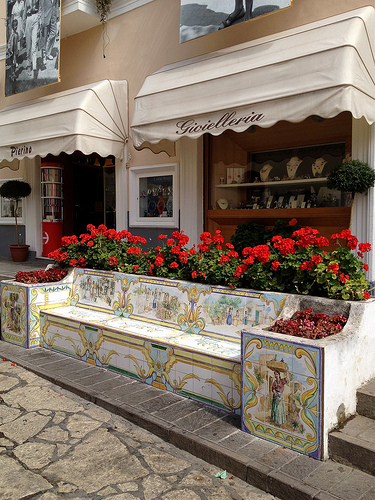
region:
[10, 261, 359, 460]
An old cement bench with paintings on it.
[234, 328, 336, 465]
The painting of a woman with a basket on her head.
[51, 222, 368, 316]
Red potted flowers on top of the bench.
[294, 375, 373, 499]
Steps leading up to the shops.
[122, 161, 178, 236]
A window with watches on display.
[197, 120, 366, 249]
A window display with jewelry in it.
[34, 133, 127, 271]
The entrance to the shops.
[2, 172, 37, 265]
A potted tree by the entrance.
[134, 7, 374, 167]
A window awning for Gioielleria.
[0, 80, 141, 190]
A window awning for Pierino.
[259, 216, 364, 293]
geraniums in full bloom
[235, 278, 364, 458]
ornate tile and masonry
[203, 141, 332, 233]
shop window jewlery display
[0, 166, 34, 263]
potted topiary evergreen tree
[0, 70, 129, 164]
custom outdoor shop awning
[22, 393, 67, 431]
outdoor flagstone street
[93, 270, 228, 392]
scenic tiled outdoor bench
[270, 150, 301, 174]
necklace on display easel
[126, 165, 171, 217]
outside shop window watch display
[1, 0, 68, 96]
outdoor hanging monochromatic artwork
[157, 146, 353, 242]
jewelry in a store window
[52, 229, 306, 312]
Red flowers on the back of a bench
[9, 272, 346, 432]
A tile bench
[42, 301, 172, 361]
The seat of a bench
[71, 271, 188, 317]
The back of a bench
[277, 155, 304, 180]
A necklace in a store window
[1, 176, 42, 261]
A tree in a pot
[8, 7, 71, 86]
A black and white picture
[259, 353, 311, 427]
A woman with a basket on her head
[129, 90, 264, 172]
A white awning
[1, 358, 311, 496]
the street next to the building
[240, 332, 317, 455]
a picture in the tiles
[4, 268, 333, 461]
a bench with a lot of colorful tiles on it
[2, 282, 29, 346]
another painting made out of tiles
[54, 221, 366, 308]
red flowers growing on top of the bench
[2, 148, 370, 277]
two buildings behind the bench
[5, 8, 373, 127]
the awnings above the stores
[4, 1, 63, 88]
a poster above the building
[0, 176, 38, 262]
a tree next to the store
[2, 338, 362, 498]
the sidewalk in front of the bench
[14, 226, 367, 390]
Ornate vintage planted seating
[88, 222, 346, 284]
Red geraniums healthy plants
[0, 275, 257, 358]
Hand painted artwork bench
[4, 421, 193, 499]
Inlaid stone covers street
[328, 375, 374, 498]
Right brick stairs descend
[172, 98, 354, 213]
Awning jewelry shop Gioielleria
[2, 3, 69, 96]
Large black white photo hangs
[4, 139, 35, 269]
Potted tree outside Pierino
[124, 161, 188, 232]
Goods small window display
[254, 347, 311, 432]
Artistic painting village girl